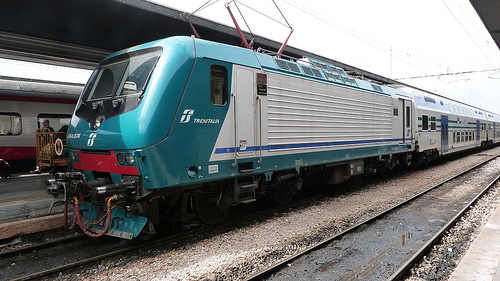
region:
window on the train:
[210, 65, 230, 104]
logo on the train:
[176, 104, 222, 127]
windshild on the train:
[97, 55, 152, 91]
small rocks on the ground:
[198, 235, 244, 262]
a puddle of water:
[392, 233, 417, 248]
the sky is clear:
[392, 9, 442, 36]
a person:
[35, 115, 54, 132]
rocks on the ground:
[451, 232, 473, 246]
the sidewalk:
[481, 239, 498, 256]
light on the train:
[149, 73, 171, 98]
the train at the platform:
[57, 39, 462, 182]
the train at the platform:
[36, 0, 433, 279]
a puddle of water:
[348, 199, 436, 279]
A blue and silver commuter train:
[55, 1, 497, 232]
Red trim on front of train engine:
[45, 112, 163, 240]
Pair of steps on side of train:
[226, 98, 270, 207]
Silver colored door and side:
[235, 63, 415, 163]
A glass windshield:
[86, 58, 155, 105]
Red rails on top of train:
[179, 1, 406, 78]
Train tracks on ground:
[18, 218, 115, 269]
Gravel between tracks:
[203, 207, 287, 260]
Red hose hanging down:
[64, 193, 132, 237]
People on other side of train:
[13, 106, 58, 175]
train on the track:
[92, 40, 490, 191]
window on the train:
[420, 116, 432, 133]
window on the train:
[427, 115, 439, 132]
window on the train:
[451, 129, 461, 145]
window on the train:
[460, 133, 465, 142]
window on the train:
[457, 125, 468, 145]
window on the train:
[467, 130, 470, 140]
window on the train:
[471, 131, 475, 143]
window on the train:
[89, 59, 149, 88]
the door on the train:
[235, 63, 259, 160]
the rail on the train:
[252, 91, 267, 166]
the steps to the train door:
[233, 171, 261, 206]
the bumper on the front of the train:
[43, 168, 137, 207]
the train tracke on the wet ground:
[306, 197, 439, 279]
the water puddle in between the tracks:
[386, 225, 414, 253]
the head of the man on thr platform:
[38, 113, 60, 131]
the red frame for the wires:
[178, 0, 298, 56]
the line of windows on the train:
[446, 124, 478, 146]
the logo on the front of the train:
[171, 103, 226, 136]